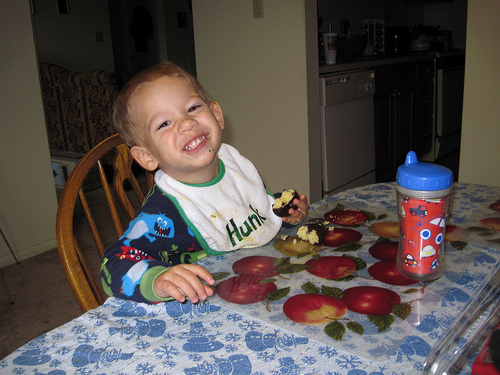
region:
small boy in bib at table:
[96, 63, 313, 311]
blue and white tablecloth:
[10, 168, 498, 370]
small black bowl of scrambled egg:
[270, 188, 340, 251]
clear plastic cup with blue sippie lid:
[392, 148, 462, 283]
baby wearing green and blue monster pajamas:
[106, 165, 282, 309]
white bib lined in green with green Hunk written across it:
[162, 135, 288, 250]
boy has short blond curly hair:
[110, 61, 222, 163]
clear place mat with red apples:
[219, 191, 486, 362]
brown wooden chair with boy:
[57, 131, 249, 311]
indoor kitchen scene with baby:
[2, 6, 497, 363]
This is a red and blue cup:
[378, 145, 476, 292]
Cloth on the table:
[87, 307, 247, 372]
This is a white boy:
[60, 47, 335, 322]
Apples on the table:
[281, 267, 423, 347]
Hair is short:
[81, 57, 205, 149]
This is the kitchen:
[298, 0, 474, 190]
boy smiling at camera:
[119, 63, 249, 217]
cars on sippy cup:
[379, 200, 454, 284]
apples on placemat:
[303, 262, 390, 334]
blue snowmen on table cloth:
[68, 338, 135, 366]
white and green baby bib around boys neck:
[166, 142, 276, 267]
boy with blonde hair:
[102, 63, 254, 173]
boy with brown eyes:
[136, 88, 229, 145]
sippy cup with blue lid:
[395, 145, 474, 278]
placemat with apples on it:
[185, 193, 436, 327]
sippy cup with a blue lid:
[381, 150, 473, 277]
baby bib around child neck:
[152, 138, 277, 252]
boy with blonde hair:
[107, 58, 232, 197]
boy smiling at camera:
[119, 55, 238, 180]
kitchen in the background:
[292, 2, 459, 177]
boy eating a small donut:
[256, 180, 334, 250]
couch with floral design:
[33, 62, 118, 153]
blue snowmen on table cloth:
[72, 334, 132, 372]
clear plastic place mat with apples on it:
[190, 192, 495, 366]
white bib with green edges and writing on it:
[150, 139, 287, 260]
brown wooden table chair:
[50, 126, 177, 314]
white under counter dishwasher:
[314, 60, 382, 202]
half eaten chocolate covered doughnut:
[267, 183, 308, 222]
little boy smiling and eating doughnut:
[92, 50, 315, 307]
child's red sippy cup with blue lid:
[390, 143, 458, 288]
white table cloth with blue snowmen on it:
[2, 173, 498, 373]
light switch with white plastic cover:
[248, 0, 267, 22]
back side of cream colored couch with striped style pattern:
[34, 57, 127, 163]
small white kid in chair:
[99, 59, 311, 304]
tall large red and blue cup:
[397, 149, 452, 278]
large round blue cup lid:
[398, 149, 453, 194]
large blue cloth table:
[0, 176, 499, 373]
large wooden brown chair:
[56, 130, 157, 315]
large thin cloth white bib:
[153, 144, 283, 253]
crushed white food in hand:
[271, 188, 299, 217]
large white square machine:
[318, 65, 383, 197]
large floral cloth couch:
[39, 67, 124, 183]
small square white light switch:
[251, 1, 263, 19]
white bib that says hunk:
[153, 142, 281, 257]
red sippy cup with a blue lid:
[393, 150, 453, 280]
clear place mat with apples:
[196, 195, 482, 359]